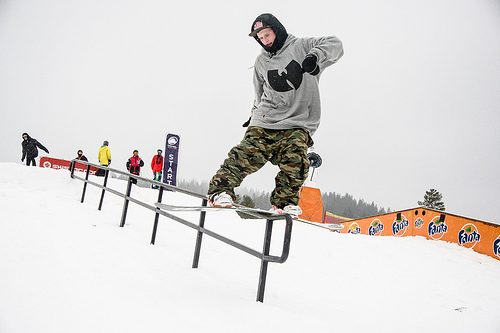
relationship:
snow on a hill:
[354, 232, 429, 268] [15, 152, 261, 244]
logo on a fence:
[422, 213, 445, 236] [348, 202, 499, 261]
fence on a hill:
[348, 202, 499, 261] [15, 152, 261, 244]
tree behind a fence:
[418, 184, 442, 210] [348, 202, 499, 261]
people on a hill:
[16, 130, 166, 189] [15, 152, 261, 244]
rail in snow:
[64, 156, 302, 271] [354, 232, 429, 268]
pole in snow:
[248, 253, 273, 307] [354, 232, 429, 268]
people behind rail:
[16, 130, 166, 189] [64, 156, 307, 304]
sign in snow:
[165, 130, 179, 191] [354, 232, 429, 268]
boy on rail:
[216, 5, 321, 221] [64, 156, 307, 304]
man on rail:
[216, 5, 321, 221] [64, 156, 302, 271]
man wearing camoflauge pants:
[216, 5, 321, 221] [217, 116, 314, 208]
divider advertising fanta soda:
[415, 199, 496, 250] [428, 214, 485, 250]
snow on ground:
[354, 232, 429, 268] [330, 293, 499, 326]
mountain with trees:
[157, 176, 411, 250] [171, 170, 410, 225]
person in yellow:
[94, 135, 114, 178] [100, 150, 110, 166]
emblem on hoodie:
[262, 57, 303, 93] [242, 41, 332, 142]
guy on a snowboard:
[216, 5, 321, 221] [153, 191, 302, 221]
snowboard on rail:
[153, 201, 344, 232] [64, 156, 307, 304]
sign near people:
[165, 130, 179, 191] [16, 130, 166, 189]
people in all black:
[17, 132, 51, 167] [24, 139, 35, 160]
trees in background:
[171, 170, 410, 225] [191, 136, 372, 196]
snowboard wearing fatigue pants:
[153, 201, 344, 232] [241, 129, 299, 203]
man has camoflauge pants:
[216, 5, 321, 221] [217, 116, 314, 208]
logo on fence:
[422, 213, 445, 236] [348, 202, 499, 261]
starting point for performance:
[164, 132, 174, 189] [148, 10, 397, 260]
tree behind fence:
[418, 184, 442, 210] [348, 202, 499, 261]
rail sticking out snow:
[64, 156, 307, 304] [354, 232, 429, 268]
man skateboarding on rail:
[216, 5, 321, 221] [64, 156, 302, 271]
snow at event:
[354, 232, 429, 268] [19, 101, 490, 290]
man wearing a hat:
[216, 5, 321, 221] [246, 16, 268, 39]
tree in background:
[418, 184, 442, 210] [191, 136, 372, 196]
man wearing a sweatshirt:
[216, 5, 321, 221] [242, 41, 332, 142]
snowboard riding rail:
[153, 201, 344, 232] [64, 156, 302, 271]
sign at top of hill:
[165, 130, 179, 191] [15, 152, 261, 244]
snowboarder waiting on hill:
[16, 130, 166, 189] [15, 152, 261, 244]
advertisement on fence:
[379, 208, 499, 257] [348, 202, 499, 261]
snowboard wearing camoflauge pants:
[153, 201, 344, 232] [217, 116, 314, 208]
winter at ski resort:
[303, 218, 423, 313] [7, 112, 486, 315]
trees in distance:
[171, 170, 410, 225] [183, 111, 237, 127]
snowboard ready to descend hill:
[153, 201, 344, 232] [15, 152, 261, 244]